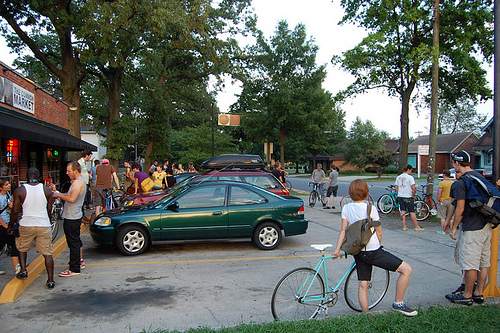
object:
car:
[89, 178, 310, 256]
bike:
[271, 243, 393, 323]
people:
[51, 162, 86, 276]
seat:
[309, 243, 334, 253]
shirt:
[63, 175, 90, 220]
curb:
[0, 210, 89, 301]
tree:
[325, 0, 496, 178]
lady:
[0, 172, 30, 279]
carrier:
[200, 154, 265, 169]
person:
[330, 178, 419, 320]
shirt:
[134, 170, 149, 183]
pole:
[425, 16, 441, 210]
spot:
[67, 252, 341, 266]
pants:
[64, 212, 82, 279]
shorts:
[13, 226, 55, 255]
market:
[0, 65, 95, 208]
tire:
[252, 218, 284, 250]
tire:
[270, 267, 323, 324]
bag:
[337, 205, 383, 256]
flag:
[217, 113, 241, 128]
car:
[119, 170, 293, 209]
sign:
[211, 114, 243, 155]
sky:
[237, 0, 360, 53]